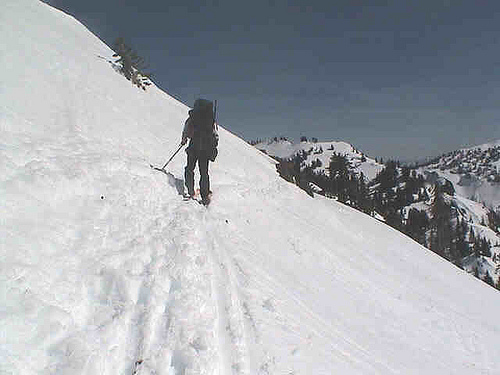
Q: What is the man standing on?
A: Skis.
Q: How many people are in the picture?
A: One.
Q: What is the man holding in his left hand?
A: Ski pole.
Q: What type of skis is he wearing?
A: Cross country.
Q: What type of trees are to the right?
A: Pine trees.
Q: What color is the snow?
A: White.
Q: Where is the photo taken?
A: Ski slope.